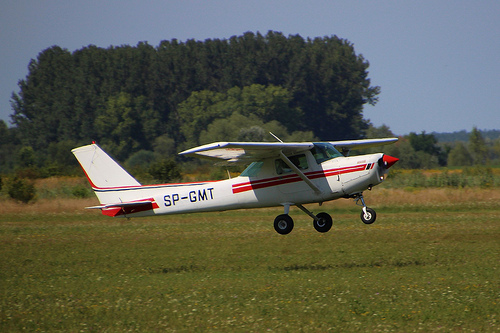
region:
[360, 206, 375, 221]
the wheel of a plane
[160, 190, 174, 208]
a black capital letter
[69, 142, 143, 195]
the tail of a plane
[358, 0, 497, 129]
part of a blue sky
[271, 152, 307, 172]
the window of a plane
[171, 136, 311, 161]
the wing of a plane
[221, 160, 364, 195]
a long red and white line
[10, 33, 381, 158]
a tall set of green trees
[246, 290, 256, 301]
a small white flower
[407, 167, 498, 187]
tall green grass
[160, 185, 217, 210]
plane's name or whatever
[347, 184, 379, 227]
retractable wheel on the bottom front of the plane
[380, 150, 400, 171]
red cone-like nose of the plane where the propeller is...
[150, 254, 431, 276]
very narrow and long shadow of the plane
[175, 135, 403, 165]
the wide wingspan of the white plane wings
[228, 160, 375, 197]
long double stripe going down the side of the plane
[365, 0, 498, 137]
large open expanse in the trees and brush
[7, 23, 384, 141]
large close together area of pine trees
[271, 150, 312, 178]
small side window of the plane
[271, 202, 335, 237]
primary wheels of the plane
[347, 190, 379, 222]
Landing gear on an airplane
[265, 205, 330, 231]
Wheels on an airplane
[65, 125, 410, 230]
A red and white airplane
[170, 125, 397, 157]
The wings on an airplane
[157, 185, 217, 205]
The identification numbers on an airplane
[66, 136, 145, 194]
The tail of an airplane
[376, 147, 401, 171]
The nose cone and propeller on an airplane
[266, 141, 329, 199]
Struts supporting the wing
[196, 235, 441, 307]
Grassy field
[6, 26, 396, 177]
Tall trees near a runway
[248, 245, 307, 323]
part of a ground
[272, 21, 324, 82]
part of a forest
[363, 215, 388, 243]
part of a wheel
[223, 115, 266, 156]
edge of a wing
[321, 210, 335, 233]
part of a wheel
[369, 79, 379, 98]
edge of a tree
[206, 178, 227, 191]
part of a plane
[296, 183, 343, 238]
part of a wheel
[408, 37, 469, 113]
part of the sky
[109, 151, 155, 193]
edge of a wing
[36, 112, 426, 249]
A private airplane taking off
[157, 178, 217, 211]
Black writing on the side of the plane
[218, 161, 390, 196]
A red stripe on the side of the plane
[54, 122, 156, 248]
The tail end of the plane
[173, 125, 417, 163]
The wings on the airplane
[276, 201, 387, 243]
The wheels on the plane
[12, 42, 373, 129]
A large set of trees with green leaves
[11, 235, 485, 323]
A large patch of green grass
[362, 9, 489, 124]
A blue grey sky looks like an overcast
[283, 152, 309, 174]
A pilot in the cockpit